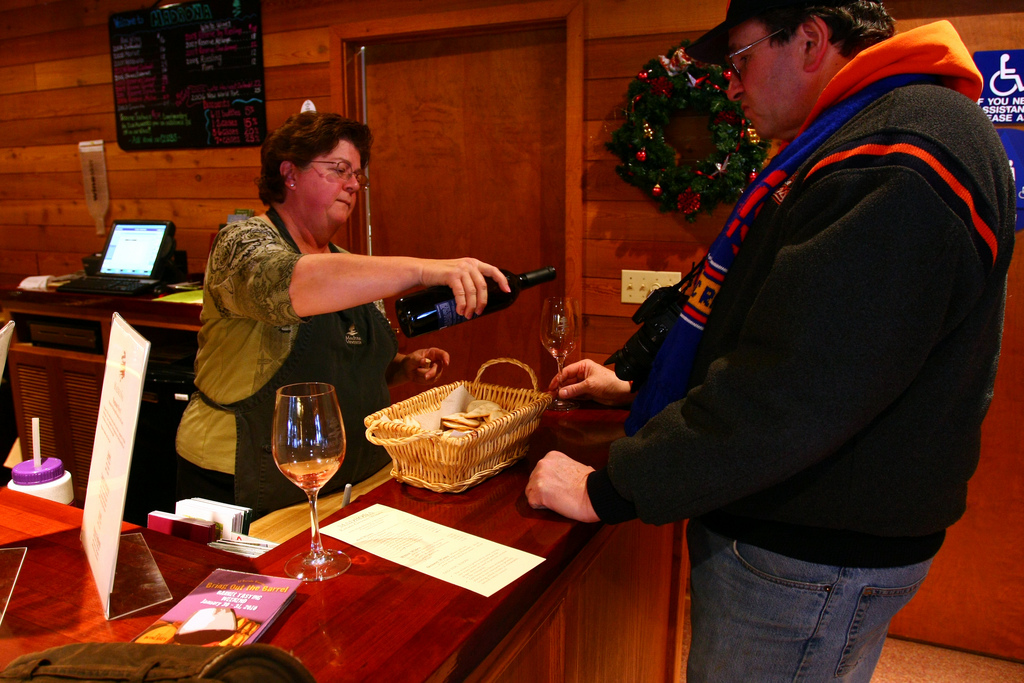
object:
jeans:
[688, 533, 934, 682]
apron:
[173, 207, 398, 508]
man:
[525, 0, 1017, 679]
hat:
[684, 1, 894, 66]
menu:
[128, 570, 304, 650]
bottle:
[395, 269, 556, 340]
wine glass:
[273, 382, 353, 582]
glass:
[539, 297, 582, 410]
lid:
[6, 458, 64, 486]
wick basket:
[362, 358, 553, 494]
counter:
[2, 476, 597, 679]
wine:
[544, 264, 566, 318]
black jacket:
[785, 246, 965, 417]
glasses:
[722, 35, 771, 82]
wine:
[395, 265, 556, 340]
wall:
[109, 151, 260, 210]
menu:
[106, 0, 267, 153]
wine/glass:
[395, 265, 582, 410]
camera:
[603, 258, 705, 382]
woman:
[175, 113, 511, 512]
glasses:
[312, 161, 370, 186]